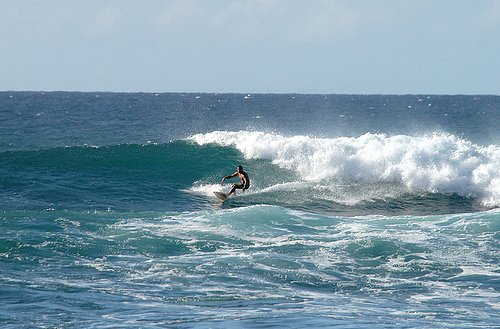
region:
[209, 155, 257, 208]
a man surfing in the ocean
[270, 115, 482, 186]
a large wave in the ocean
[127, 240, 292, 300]
a blue ocean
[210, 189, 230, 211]
the mans surfboard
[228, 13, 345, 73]
the sky is clear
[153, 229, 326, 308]
ripples in the water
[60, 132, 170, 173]
the back of the wave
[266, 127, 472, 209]
the wave crashing down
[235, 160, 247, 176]
the mans head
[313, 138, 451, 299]
seafoam in the ocean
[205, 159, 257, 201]
the surfer on the water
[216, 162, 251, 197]
the surfer holding his arm out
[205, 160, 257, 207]
the man rides the waves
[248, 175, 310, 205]
the water splashing into the air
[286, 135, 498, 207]
the wave crashing behind the man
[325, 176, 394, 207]
the water splashing in front of the wave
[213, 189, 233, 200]
the board under the feet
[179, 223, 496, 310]
the foam on the top of the water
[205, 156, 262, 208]
the man riding standing on the board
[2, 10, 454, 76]
the cloudless blue sky above the ocean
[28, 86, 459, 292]
a man surfing on the waves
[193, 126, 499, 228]
these waves look rough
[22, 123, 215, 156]
the top part of the wave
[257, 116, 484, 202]
the waves are white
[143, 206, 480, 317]
this water is agitated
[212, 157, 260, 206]
the surfer is not wearing a shirt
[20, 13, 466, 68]
blue skies above the ocean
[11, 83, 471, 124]
this part of the ocean is calm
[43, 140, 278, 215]
this surfer is moving across the top of the water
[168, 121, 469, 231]
the surfer is outrunning the wave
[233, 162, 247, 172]
head of a person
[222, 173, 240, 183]
arm of a person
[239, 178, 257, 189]
arm of a person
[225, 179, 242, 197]
leg of a person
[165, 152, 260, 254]
person surfing on a board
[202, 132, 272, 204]
person riding a wave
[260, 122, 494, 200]
waves of an ocean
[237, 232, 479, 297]
a clear body of water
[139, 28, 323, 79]
clear blue skies with no clouds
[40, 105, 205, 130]
a body of water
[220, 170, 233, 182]
arm of a person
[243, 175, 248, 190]
arm of a person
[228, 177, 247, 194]
leg of a person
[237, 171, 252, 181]
body of a person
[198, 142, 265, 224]
person on a surf board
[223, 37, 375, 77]
clear blue sky with no clouds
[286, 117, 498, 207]
waves of an ocean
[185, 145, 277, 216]
person surfing on water